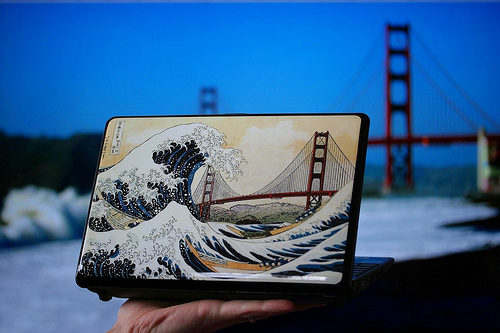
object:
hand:
[97, 292, 332, 332]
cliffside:
[4, 134, 105, 188]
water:
[102, 119, 242, 281]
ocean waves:
[110, 132, 302, 275]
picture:
[74, 112, 371, 291]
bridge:
[340, 17, 497, 180]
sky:
[0, 2, 493, 167]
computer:
[71, 110, 371, 302]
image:
[81, 100, 371, 285]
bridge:
[191, 132, 358, 220]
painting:
[79, 117, 357, 295]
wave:
[110, 127, 249, 207]